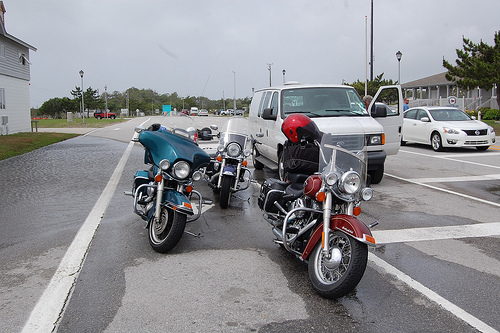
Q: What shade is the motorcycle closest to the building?
A: Turquoise.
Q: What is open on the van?
A: The door.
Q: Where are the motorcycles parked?
A: On the street.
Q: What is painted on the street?
A: White lines.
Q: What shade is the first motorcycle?
A: Red.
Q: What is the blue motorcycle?
A: Parked.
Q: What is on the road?
A: White line.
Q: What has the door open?
A: White van.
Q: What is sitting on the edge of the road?
A: Red motorcycle.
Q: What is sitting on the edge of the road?
A: Blue motorcycle.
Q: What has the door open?
A: The white van.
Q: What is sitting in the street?
A: The red motorcycle.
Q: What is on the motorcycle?
A: The windshield.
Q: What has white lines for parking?
A: The street.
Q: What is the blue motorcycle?
A: Parked.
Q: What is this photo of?
A: A street scene.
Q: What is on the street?
A: White lines.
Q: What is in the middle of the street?
A: Bikes.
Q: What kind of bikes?
A: Motorcycles.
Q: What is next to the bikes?
A: Parked cars.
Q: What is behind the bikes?
A: Traffic.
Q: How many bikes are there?
A: 4.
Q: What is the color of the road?
A: Grey.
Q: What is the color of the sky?
A: Blue.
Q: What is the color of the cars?
A: White.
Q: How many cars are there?
A: 2.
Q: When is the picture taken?
A: Daytime.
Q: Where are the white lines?
A: In the road.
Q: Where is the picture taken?
A: On the street.